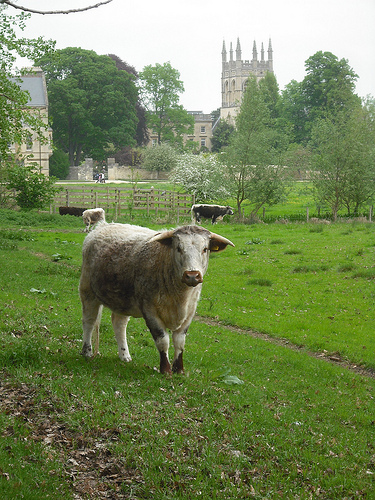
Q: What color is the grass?
A: Green.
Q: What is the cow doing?
A: Standing.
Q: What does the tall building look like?
A: A castle.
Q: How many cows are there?
A: 3.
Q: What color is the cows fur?
A: Dirty white.